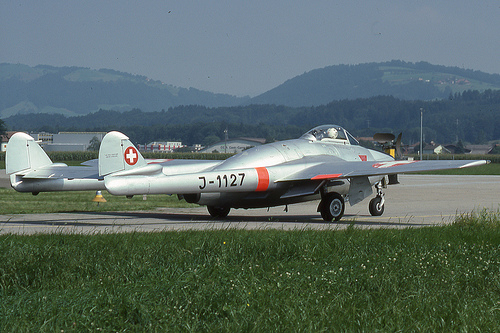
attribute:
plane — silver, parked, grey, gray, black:
[76, 108, 437, 206]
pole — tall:
[412, 107, 434, 161]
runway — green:
[411, 180, 449, 213]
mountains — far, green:
[137, 81, 197, 114]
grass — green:
[381, 251, 440, 288]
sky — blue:
[208, 16, 255, 42]